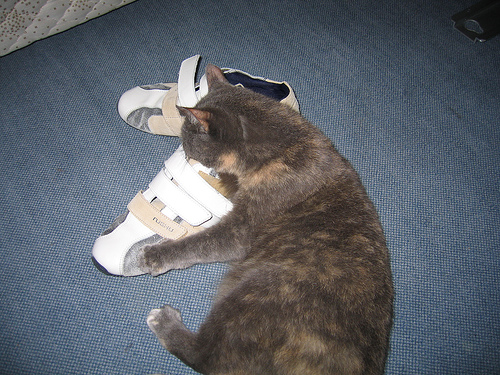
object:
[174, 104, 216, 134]
ear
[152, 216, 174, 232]
writing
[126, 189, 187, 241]
strap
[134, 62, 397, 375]
cat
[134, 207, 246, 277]
leg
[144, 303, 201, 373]
leg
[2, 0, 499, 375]
carpet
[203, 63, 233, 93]
ear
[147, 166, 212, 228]
strap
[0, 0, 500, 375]
surface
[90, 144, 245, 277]
shoe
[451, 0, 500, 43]
metal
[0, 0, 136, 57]
fabric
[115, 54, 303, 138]
shoe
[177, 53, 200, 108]
straps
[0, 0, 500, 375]
ground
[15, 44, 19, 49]
spots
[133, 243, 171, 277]
paw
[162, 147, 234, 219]
strap